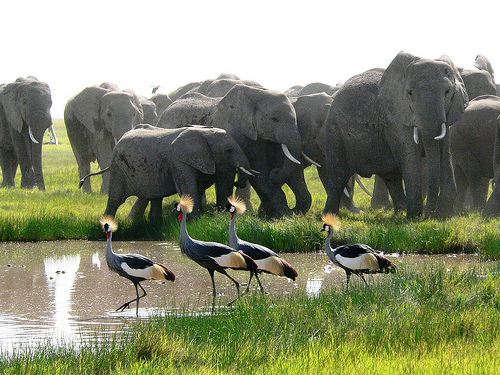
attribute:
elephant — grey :
[66, 80, 140, 204]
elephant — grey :
[320, 55, 470, 217]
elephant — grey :
[1, 73, 61, 190]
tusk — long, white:
[280, 142, 300, 164]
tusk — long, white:
[301, 150, 321, 167]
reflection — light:
[42, 250, 79, 342]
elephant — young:
[78, 121, 254, 225]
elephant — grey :
[291, 48, 483, 176]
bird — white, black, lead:
[92, 217, 177, 322]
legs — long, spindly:
[119, 287, 153, 321]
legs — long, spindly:
[202, 273, 242, 313]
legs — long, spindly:
[237, 275, 265, 308]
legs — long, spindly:
[338, 271, 377, 298]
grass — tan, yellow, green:
[5, 272, 498, 370]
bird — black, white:
[74, 192, 180, 324]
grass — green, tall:
[163, 262, 498, 353]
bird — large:
[90, 222, 177, 316]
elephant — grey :
[68, 122, 276, 200]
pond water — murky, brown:
[4, 247, 104, 345]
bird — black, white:
[303, 204, 420, 286]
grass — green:
[49, 205, 474, 248]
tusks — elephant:
[339, 180, 351, 201]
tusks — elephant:
[352, 171, 376, 196]